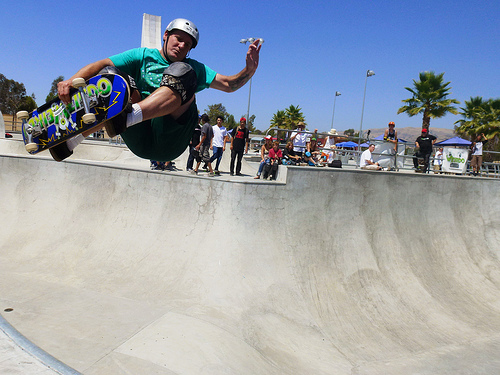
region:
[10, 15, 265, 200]
The man is skateboarding.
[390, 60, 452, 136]
A palm tree.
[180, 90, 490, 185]
Teenagers hanging out.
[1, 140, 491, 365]
A large empty pool.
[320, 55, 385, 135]
Streetlights.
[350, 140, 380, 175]
The person is wearing a white t-shirt.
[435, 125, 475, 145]
A large blue umbrella.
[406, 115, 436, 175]
The man is wearing a red hat.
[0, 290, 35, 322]
A drain.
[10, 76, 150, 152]
Skateboard with a blue bottom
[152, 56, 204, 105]
Black kneepad on skateboarding man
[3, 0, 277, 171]
Skateboarding man in green shirt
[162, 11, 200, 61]
Silver helmet on skateboarding man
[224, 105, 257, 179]
Onlooker in black and red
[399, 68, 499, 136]
Palm trees behind the people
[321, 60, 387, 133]
Lightposts in background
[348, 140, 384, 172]
Man sitting in white shirt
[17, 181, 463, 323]
Skateboard park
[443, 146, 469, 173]
Small sign with green text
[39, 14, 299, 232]
man doing trick on skateboard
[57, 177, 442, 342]
curved cement skateboard ramp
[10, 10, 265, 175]
man is in mid air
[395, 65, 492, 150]
palm trees in the background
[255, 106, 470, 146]
hills in the far distance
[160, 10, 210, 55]
man wearing silver helmet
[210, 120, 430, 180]
people are watching the skateboarder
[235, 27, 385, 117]
lights on tall poles in the background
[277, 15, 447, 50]
blue sky with no clouds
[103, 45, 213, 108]
man wearing green shirt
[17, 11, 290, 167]
man on a skateboard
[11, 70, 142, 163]
blue skateboard with green lettering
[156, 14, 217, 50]
wearing a safety helmet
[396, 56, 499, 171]
two palm trees behind fence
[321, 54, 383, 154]
two tall lamp posts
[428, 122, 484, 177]
blue portable pop-up tent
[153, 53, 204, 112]
skater wearing knee pads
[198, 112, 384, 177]
people watching man on skateboard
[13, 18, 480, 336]
people in a skateboard park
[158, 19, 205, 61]
the head of a man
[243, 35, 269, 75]
the hand of a man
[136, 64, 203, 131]
the leg of a man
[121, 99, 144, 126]
a white sock on the man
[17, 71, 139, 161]
a skateboard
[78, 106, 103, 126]
a white skateboard wheel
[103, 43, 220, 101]
an aqua tee shirt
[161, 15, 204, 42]
a gray helmet on the man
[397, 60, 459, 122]
a green tree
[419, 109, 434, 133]
the trunk of a tree